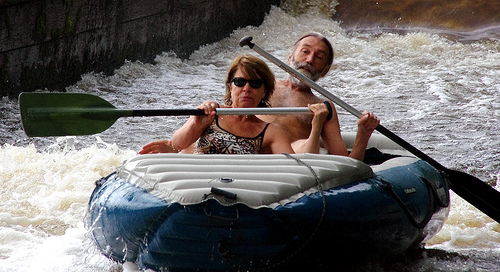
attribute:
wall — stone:
[1, 2, 262, 87]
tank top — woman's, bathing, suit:
[167, 53, 292, 176]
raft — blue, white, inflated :
[81, 145, 455, 270]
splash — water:
[0, 122, 98, 242]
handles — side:
[380, 168, 470, 223]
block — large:
[3, 0, 273, 99]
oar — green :
[18, 87, 335, 136]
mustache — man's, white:
[282, 56, 318, 86]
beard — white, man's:
[283, 56, 315, 87]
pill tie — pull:
[202, 187, 251, 204]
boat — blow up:
[101, 112, 458, 264]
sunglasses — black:
[225, 72, 270, 89]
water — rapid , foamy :
[390, 40, 484, 118]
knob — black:
[232, 30, 263, 58]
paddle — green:
[19, 91, 120, 133]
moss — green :
[39, 19, 59, 58]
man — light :
[256, 29, 379, 159]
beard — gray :
[289, 55, 320, 85]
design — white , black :
[199, 130, 217, 148]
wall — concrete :
[10, 8, 120, 68]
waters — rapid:
[1, 11, 481, 270]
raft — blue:
[79, 108, 456, 270]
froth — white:
[0, 130, 115, 222]